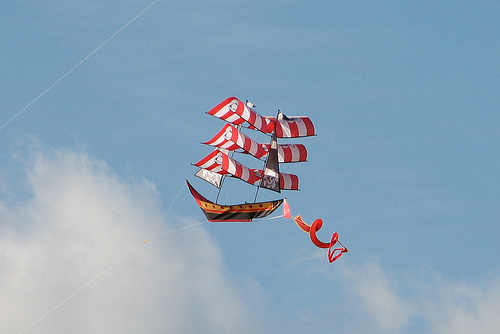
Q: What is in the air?
A: A kite.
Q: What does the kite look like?
A: A ship.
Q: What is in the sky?
A: Cloud.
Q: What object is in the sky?
A: Kite.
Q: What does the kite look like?
A: Ship.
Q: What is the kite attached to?
A: String.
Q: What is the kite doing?
A: Flying.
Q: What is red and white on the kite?
A: Sails.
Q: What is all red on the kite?
A: Tail.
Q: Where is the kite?
A: In sky.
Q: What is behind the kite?
A: Clouds.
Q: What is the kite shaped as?
A: A ship.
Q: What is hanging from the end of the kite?
A: Tail.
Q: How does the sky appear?
A: Cloudy.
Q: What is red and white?
A: Sails.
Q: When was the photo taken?
A: In the daytime.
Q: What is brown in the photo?
A: Boat.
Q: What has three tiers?
A: Sails.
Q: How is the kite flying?
A: By string.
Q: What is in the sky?
A: Kite.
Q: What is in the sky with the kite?
A: Clouds.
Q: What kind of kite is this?
A: Red and white striped and multi colored.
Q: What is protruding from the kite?
A: Kite tail.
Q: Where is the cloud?
A: Lower left hand side.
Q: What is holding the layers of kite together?
A: Black string.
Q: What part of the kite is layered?
A: Red and white part.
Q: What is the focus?
A: Kite.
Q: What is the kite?
A: Pirate ship.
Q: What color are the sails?
A: Red, white.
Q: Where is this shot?
A: Sky.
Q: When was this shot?
A: Daytime.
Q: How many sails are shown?
A: 7.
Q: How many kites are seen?
A: 1.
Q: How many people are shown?
A: 0.